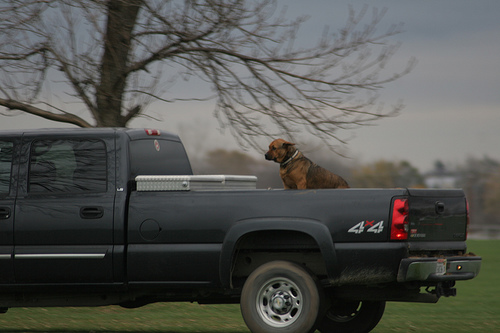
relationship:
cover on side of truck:
[135, 217, 163, 239] [1, 123, 484, 332]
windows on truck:
[31, 139, 108, 199] [1, 123, 484, 332]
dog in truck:
[263, 139, 350, 187] [1, 123, 484, 332]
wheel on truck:
[239, 261, 328, 332] [1, 123, 484, 332]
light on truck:
[386, 196, 411, 243] [1, 123, 484, 332]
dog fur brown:
[263, 139, 350, 187] [289, 166, 306, 185]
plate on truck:
[433, 258, 448, 275] [1, 123, 484, 332]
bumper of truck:
[398, 254, 485, 280] [1, 123, 484, 332]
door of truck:
[13, 130, 116, 281] [1, 123, 484, 332]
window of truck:
[31, 139, 108, 199] [1, 123, 484, 332]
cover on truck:
[135, 217, 163, 239] [1, 123, 484, 332]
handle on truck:
[81, 205, 102, 219] [1, 123, 484, 332]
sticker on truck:
[151, 140, 165, 156] [1, 123, 484, 332]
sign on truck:
[347, 218, 387, 237] [1, 123, 484, 332]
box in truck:
[137, 171, 260, 196] [1, 123, 484, 332]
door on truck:
[13, 130, 116, 281] [1, 123, 484, 332]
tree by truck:
[1, 0, 415, 154] [1, 123, 484, 332]